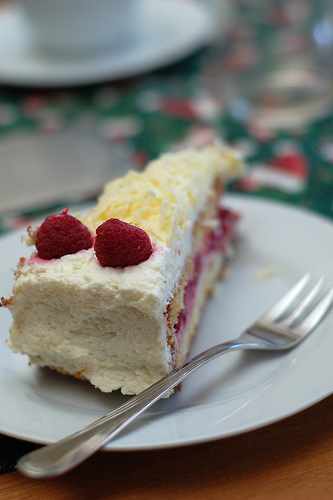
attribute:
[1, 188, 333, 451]
dish — white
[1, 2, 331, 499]
table — wooden, brown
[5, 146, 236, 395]
cake — white, yellow, piece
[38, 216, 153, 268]
berries — red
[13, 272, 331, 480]
fork — silver, small, metal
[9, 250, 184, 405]
frosting — white, yellow, fluffy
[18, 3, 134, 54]
cup — white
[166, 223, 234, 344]
filling — red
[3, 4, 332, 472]
tablecloth — green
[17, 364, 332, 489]
plate — white, blurry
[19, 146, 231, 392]
slice — dessert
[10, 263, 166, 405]
back — white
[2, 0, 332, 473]
runner — red, green, white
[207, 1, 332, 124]
glass — clear